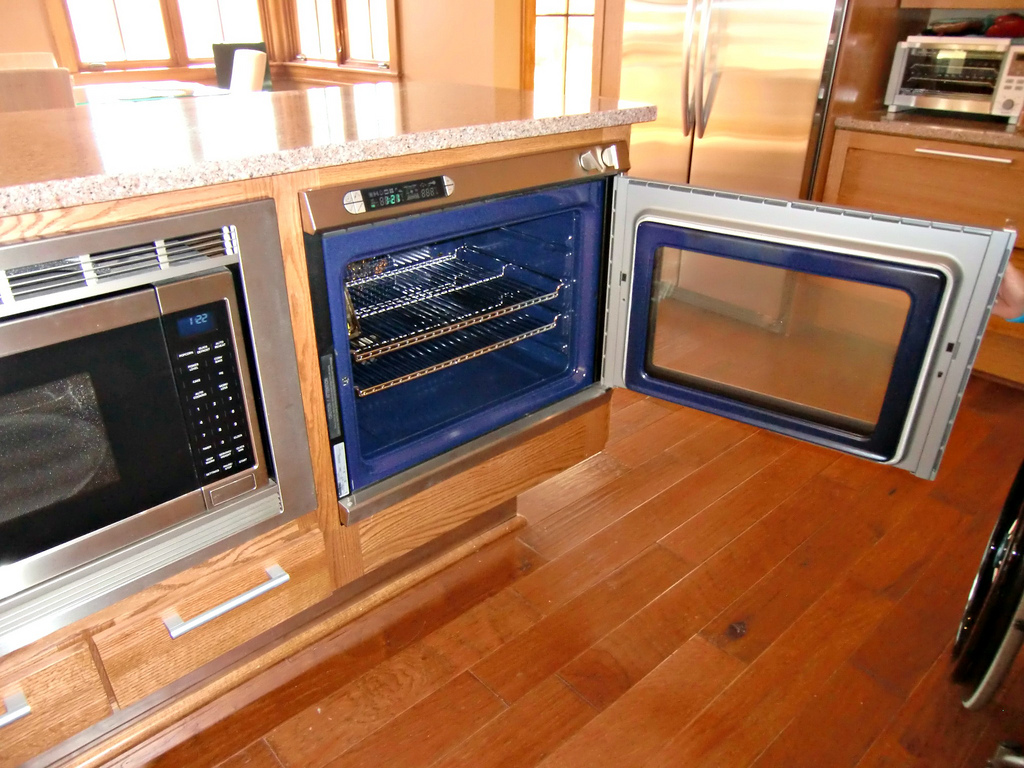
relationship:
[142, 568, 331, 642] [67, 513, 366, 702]
handle on drawer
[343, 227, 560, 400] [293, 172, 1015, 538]
racks in oven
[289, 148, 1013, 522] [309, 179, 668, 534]
oven with blue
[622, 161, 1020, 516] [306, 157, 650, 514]
door of oven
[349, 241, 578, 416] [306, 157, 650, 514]
racks inside oven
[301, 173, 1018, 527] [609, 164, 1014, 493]
oven with door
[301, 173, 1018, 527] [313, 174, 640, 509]
oven with interior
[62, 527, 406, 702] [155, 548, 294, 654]
drawer with handle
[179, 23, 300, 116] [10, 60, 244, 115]
chair at table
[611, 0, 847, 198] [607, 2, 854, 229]
refrigerator with doors